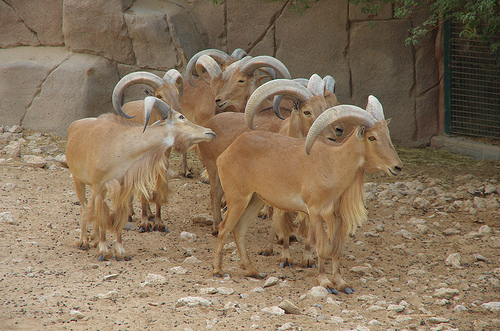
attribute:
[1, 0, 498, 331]
animal enclosure — rocky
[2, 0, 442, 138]
wall — rocks, large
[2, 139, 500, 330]
ground — dirt, rocky, sandy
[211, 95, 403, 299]
goat — hairy, brown, leading, tan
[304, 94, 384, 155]
horns — large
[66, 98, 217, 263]
goat — hairy, turning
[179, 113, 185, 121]
eye — black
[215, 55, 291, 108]
goat — tan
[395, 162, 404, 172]
nose — black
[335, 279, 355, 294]
foot — black, small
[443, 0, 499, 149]
fence — metal